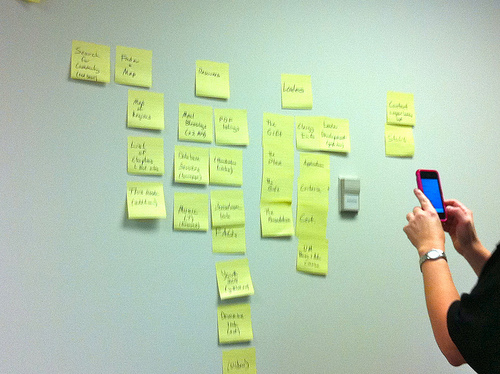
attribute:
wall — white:
[25, 115, 69, 182]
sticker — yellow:
[69, 30, 112, 81]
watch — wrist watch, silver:
[420, 241, 445, 265]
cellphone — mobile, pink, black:
[418, 163, 452, 218]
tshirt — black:
[447, 270, 499, 342]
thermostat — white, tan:
[315, 164, 372, 223]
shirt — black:
[456, 286, 498, 355]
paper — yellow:
[128, 174, 159, 217]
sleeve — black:
[446, 303, 471, 346]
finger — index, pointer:
[413, 183, 438, 212]